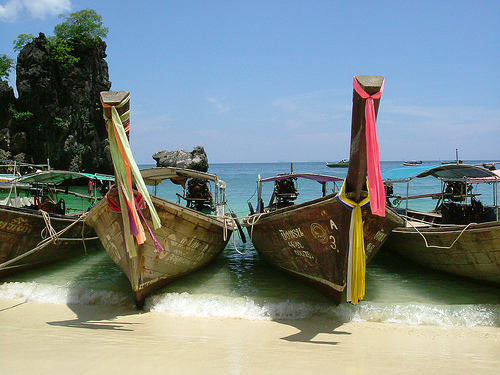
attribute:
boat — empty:
[80, 83, 241, 309]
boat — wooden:
[248, 74, 394, 322]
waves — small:
[126, 152, 498, 262]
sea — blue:
[117, 154, 497, 272]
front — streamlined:
[340, 72, 392, 306]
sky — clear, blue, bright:
[2, 0, 496, 160]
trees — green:
[0, 8, 110, 172]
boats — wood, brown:
[1, 75, 498, 309]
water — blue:
[0, 160, 498, 324]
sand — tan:
[2, 295, 496, 373]